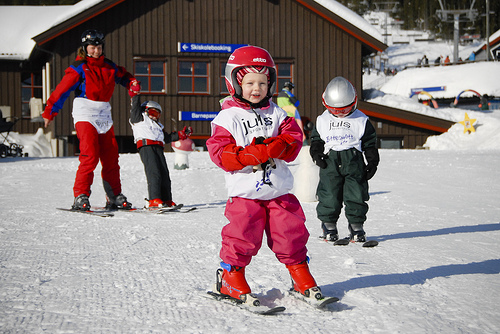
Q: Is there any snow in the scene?
A: Yes, there is snow.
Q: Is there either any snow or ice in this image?
A: Yes, there is snow.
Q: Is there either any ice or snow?
A: Yes, there is snow.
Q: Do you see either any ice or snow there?
A: Yes, there is snow.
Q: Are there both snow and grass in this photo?
A: No, there is snow but no grass.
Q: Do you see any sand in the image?
A: No, there is no sand.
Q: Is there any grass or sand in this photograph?
A: No, there are no sand or grass.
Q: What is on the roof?
A: The snow is on the roof.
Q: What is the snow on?
A: The snow is on the roof.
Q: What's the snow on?
A: The snow is on the roof.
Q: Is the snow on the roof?
A: Yes, the snow is on the roof.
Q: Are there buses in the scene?
A: No, there are no buses.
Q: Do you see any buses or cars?
A: No, there are no buses or cars.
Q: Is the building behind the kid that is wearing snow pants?
A: Yes, the building is behind the kid.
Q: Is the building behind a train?
A: No, the building is behind the kid.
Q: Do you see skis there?
A: Yes, there are skis.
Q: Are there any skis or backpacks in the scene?
A: Yes, there are skis.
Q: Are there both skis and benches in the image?
A: No, there are skis but no benches.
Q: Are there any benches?
A: No, there are no benches.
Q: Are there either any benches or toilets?
A: No, there are no benches or toilets.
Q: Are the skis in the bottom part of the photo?
A: Yes, the skis are in the bottom of the image.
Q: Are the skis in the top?
A: No, the skis are in the bottom of the image.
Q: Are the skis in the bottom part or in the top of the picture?
A: The skis are in the bottom of the image.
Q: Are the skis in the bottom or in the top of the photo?
A: The skis are in the bottom of the image.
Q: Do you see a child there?
A: Yes, there is a child.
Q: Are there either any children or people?
A: Yes, there is a child.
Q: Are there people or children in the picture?
A: Yes, there is a child.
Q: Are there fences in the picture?
A: No, there are no fences.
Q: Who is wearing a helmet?
A: The kid is wearing a helmet.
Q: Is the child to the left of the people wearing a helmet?
A: Yes, the kid is wearing a helmet.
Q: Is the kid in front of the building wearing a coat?
A: No, the kid is wearing a helmet.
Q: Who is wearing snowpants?
A: The kid is wearing snowpants.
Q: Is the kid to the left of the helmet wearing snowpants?
A: Yes, the kid is wearing snowpants.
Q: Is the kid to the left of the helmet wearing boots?
A: No, the kid is wearing snowpants.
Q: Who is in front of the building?
A: The child is in front of the building.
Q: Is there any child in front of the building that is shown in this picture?
A: Yes, there is a child in front of the building.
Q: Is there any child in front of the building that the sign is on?
A: Yes, there is a child in front of the building.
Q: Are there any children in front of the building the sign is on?
A: Yes, there is a child in front of the building.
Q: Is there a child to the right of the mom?
A: Yes, there is a child to the right of the mom.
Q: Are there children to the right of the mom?
A: Yes, there is a child to the right of the mom.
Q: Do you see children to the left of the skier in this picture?
A: Yes, there is a child to the left of the skier.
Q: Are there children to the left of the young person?
A: Yes, there is a child to the left of the skier.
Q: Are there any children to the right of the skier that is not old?
A: No, the child is to the left of the skier.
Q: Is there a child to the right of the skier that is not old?
A: No, the child is to the left of the skier.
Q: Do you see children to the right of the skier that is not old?
A: No, the child is to the left of the skier.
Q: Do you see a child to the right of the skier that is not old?
A: No, the child is to the left of the skier.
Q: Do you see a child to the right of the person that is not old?
A: No, the child is to the left of the skier.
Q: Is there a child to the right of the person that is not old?
A: No, the child is to the left of the skier.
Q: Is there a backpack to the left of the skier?
A: No, there is a child to the left of the skier.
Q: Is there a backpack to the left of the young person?
A: No, there is a child to the left of the skier.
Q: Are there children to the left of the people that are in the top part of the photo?
A: Yes, there is a child to the left of the people.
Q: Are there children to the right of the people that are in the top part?
A: No, the child is to the left of the people.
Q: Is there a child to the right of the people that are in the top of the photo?
A: No, the child is to the left of the people.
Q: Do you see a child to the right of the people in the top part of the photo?
A: No, the child is to the left of the people.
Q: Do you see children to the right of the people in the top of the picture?
A: No, the child is to the left of the people.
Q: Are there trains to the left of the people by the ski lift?
A: No, there is a child to the left of the people.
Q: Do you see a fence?
A: No, there are no fences.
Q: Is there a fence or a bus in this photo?
A: No, there are no fences or buses.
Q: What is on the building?
A: The sign is on the building.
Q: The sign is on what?
A: The sign is on the building.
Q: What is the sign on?
A: The sign is on the building.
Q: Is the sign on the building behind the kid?
A: Yes, the sign is on the building.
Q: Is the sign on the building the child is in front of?
A: Yes, the sign is on the building.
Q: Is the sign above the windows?
A: Yes, the sign is above the windows.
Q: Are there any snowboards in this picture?
A: No, there are no snowboards.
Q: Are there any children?
A: Yes, there is a child.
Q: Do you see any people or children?
A: Yes, there is a child.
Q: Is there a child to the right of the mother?
A: Yes, there is a child to the right of the mother.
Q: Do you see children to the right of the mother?
A: Yes, there is a child to the right of the mother.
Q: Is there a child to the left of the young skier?
A: Yes, there is a child to the left of the skier.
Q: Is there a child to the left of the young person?
A: Yes, there is a child to the left of the skier.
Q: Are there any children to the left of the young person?
A: Yes, there is a child to the left of the skier.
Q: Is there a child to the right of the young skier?
A: No, the child is to the left of the skier.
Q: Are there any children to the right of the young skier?
A: No, the child is to the left of the skier.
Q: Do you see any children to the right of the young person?
A: No, the child is to the left of the skier.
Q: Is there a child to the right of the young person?
A: No, the child is to the left of the skier.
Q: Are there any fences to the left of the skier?
A: No, there is a child to the left of the skier.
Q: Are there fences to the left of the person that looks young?
A: No, there is a child to the left of the skier.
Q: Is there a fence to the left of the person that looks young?
A: No, there is a child to the left of the skier.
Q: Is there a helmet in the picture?
A: Yes, there is a helmet.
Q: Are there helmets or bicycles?
A: Yes, there is a helmet.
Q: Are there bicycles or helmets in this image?
A: Yes, there is a helmet.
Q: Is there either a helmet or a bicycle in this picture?
A: Yes, there is a helmet.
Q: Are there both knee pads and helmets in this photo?
A: No, there is a helmet but no knee pads.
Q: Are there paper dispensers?
A: No, there are no paper dispensers.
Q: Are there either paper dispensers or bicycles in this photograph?
A: No, there are no paper dispensers or bicycles.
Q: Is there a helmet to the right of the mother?
A: Yes, there is a helmet to the right of the mother.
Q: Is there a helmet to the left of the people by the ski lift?
A: Yes, there is a helmet to the left of the people.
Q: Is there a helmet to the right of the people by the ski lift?
A: No, the helmet is to the left of the people.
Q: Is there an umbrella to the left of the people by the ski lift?
A: No, there is a helmet to the left of the people.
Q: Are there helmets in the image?
A: Yes, there is a helmet.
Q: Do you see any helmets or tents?
A: Yes, there is a helmet.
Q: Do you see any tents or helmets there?
A: Yes, there is a helmet.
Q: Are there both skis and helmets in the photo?
A: Yes, there are both a helmet and skis.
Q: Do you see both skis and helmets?
A: Yes, there are both a helmet and skis.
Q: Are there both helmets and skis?
A: Yes, there are both a helmet and skis.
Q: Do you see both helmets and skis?
A: Yes, there are both a helmet and skis.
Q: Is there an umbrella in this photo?
A: No, there are no umbrellas.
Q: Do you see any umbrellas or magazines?
A: No, there are no umbrellas or magazines.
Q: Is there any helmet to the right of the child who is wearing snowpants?
A: Yes, there is a helmet to the right of the kid.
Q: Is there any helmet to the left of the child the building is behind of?
A: No, the helmet is to the right of the kid.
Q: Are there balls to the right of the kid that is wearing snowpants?
A: No, there is a helmet to the right of the kid.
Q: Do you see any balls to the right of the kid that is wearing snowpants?
A: No, there is a helmet to the right of the kid.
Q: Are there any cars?
A: No, there are no cars.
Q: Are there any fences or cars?
A: No, there are no cars or fences.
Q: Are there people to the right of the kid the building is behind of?
A: Yes, there are people to the right of the kid.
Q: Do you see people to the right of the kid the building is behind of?
A: Yes, there are people to the right of the kid.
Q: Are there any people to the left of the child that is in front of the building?
A: No, the people are to the right of the kid.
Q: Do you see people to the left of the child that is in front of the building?
A: No, the people are to the right of the kid.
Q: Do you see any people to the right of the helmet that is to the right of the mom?
A: Yes, there are people to the right of the helmet.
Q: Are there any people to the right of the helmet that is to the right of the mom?
A: Yes, there are people to the right of the helmet.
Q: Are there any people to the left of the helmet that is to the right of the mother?
A: No, the people are to the right of the helmet.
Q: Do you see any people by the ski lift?
A: Yes, there are people by the ski lift.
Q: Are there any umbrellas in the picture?
A: No, there are no umbrellas.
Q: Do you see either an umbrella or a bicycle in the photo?
A: No, there are no umbrellas or bicycles.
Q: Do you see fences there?
A: No, there are no fences.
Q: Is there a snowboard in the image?
A: No, there are no snowboards.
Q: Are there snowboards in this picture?
A: No, there are no snowboards.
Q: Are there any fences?
A: No, there are no fences.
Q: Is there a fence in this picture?
A: No, there are no fences.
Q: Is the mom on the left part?
A: Yes, the mom is on the left of the image.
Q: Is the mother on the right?
A: No, the mother is on the left of the image.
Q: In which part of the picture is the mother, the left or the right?
A: The mother is on the left of the image.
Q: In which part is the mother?
A: The mother is on the left of the image.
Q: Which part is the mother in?
A: The mother is on the left of the image.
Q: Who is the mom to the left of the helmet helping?
A: The mother is helping the kid.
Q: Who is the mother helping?
A: The mother is helping the kid.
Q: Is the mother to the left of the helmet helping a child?
A: Yes, the mom is helping a child.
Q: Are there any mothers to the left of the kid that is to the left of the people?
A: Yes, there is a mother to the left of the child.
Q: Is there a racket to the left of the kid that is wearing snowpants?
A: No, there is a mother to the left of the child.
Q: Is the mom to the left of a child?
A: Yes, the mom is to the left of a child.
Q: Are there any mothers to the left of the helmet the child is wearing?
A: Yes, there is a mother to the left of the helmet.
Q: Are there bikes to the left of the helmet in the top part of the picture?
A: No, there is a mother to the left of the helmet.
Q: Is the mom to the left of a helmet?
A: Yes, the mom is to the left of a helmet.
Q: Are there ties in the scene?
A: No, there are no ties.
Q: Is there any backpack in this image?
A: No, there are no backpacks.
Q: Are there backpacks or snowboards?
A: No, there are no backpacks or snowboards.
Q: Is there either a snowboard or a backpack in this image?
A: No, there are no backpacks or snowboards.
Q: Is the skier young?
A: Yes, the skier is young.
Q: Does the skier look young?
A: Yes, the skier is young.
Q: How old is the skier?
A: The skier is young.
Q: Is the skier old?
A: No, the skier is young.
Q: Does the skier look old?
A: No, the skier is young.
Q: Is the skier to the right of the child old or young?
A: The skier is young.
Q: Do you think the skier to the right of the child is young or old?
A: The skier is young.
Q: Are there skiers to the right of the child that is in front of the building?
A: Yes, there is a skier to the right of the kid.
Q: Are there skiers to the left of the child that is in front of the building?
A: No, the skier is to the right of the kid.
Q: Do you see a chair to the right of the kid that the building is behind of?
A: No, there is a skier to the right of the kid.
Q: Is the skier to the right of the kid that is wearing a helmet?
A: Yes, the skier is to the right of the child.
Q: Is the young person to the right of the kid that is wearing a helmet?
A: Yes, the skier is to the right of the child.